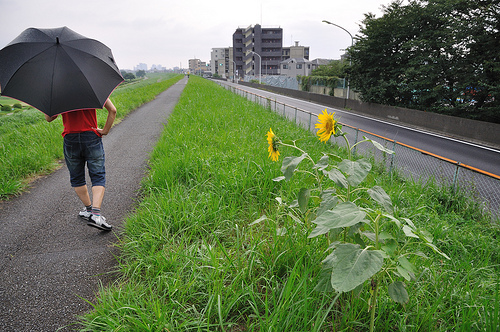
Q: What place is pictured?
A: It is a path.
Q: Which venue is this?
A: This is a path.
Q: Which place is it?
A: It is a path.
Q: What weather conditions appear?
A: It is overcast.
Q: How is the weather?
A: It is overcast.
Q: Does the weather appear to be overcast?
A: Yes, it is overcast.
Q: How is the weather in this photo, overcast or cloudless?
A: It is overcast.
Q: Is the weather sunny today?
A: No, it is overcast.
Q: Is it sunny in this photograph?
A: No, it is overcast.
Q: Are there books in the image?
A: No, there are no books.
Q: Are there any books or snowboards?
A: No, there are no books or snowboards.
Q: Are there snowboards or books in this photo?
A: No, there are no books or snowboards.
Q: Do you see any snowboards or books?
A: No, there are no books or snowboards.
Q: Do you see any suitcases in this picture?
A: No, there are no suitcases.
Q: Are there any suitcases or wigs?
A: No, there are no suitcases or wigs.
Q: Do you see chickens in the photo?
A: No, there are no chickens.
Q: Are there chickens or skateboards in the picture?
A: No, there are no chickens or skateboards.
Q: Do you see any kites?
A: No, there are no kites.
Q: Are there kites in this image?
A: No, there are no kites.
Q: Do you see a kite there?
A: No, there are no kites.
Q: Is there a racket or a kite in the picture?
A: No, there are no kites or rackets.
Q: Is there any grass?
A: Yes, there is grass.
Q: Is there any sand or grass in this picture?
A: Yes, there is grass.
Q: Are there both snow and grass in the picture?
A: No, there is grass but no snow.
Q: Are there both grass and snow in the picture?
A: No, there is grass but no snow.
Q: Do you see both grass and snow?
A: No, there is grass but no snow.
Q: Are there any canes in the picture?
A: No, there are no canes.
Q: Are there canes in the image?
A: No, there are no canes.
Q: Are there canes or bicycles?
A: No, there are no canes or bicycles.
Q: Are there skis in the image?
A: No, there are no skis.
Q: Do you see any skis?
A: No, there are no skis.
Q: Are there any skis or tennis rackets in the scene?
A: No, there are no skis or tennis rackets.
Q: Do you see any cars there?
A: No, there are no cars.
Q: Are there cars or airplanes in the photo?
A: No, there are no cars or airplanes.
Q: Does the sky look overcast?
A: Yes, the sky is overcast.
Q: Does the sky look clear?
A: No, the sky is overcast.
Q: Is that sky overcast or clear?
A: The sky is overcast.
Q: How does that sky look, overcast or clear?
A: The sky is overcast.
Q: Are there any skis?
A: No, there are no skis.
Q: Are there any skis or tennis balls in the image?
A: No, there are no skis or tennis balls.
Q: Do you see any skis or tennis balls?
A: No, there are no skis or tennis balls.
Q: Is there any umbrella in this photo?
A: Yes, there is an umbrella.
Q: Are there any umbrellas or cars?
A: Yes, there is an umbrella.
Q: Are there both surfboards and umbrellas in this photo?
A: No, there is an umbrella but no surfboards.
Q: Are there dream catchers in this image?
A: No, there are no dream catchers.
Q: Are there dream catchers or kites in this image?
A: No, there are no dream catchers or kites.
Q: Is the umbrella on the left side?
A: Yes, the umbrella is on the left of the image.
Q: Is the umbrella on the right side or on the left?
A: The umbrella is on the left of the image.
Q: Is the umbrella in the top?
A: Yes, the umbrella is in the top of the image.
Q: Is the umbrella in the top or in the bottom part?
A: The umbrella is in the top of the image.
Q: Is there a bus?
A: No, there are no buses.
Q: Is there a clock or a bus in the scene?
A: No, there are no buses or clocks.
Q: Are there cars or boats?
A: No, there are no cars or boats.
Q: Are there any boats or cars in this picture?
A: No, there are no cars or boats.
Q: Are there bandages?
A: No, there are no bandages.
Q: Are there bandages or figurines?
A: No, there are no bandages or figurines.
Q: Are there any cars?
A: No, there are no cars.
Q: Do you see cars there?
A: No, there are no cars.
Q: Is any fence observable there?
A: Yes, there is a fence.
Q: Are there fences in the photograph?
A: Yes, there is a fence.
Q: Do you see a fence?
A: Yes, there is a fence.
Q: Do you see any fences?
A: Yes, there is a fence.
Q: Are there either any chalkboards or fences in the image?
A: Yes, there is a fence.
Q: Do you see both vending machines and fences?
A: No, there is a fence but no vending machines.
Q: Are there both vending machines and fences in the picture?
A: No, there is a fence but no vending machines.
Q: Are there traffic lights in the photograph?
A: No, there are no traffic lights.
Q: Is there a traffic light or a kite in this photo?
A: No, there are no traffic lights or kites.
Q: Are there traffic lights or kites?
A: No, there are no traffic lights or kites.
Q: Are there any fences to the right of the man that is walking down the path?
A: Yes, there is a fence to the right of the man.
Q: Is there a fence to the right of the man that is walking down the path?
A: Yes, there is a fence to the right of the man.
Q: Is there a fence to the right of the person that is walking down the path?
A: Yes, there is a fence to the right of the man.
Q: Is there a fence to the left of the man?
A: No, the fence is to the right of the man.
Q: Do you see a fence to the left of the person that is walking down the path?
A: No, the fence is to the right of the man.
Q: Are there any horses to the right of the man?
A: No, there is a fence to the right of the man.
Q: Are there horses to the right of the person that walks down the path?
A: No, there is a fence to the right of the man.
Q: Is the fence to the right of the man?
A: Yes, the fence is to the right of the man.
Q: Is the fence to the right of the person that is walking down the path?
A: Yes, the fence is to the right of the man.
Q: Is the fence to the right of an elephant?
A: No, the fence is to the right of the man.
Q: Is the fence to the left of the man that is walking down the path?
A: No, the fence is to the right of the man.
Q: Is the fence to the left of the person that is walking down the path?
A: No, the fence is to the right of the man.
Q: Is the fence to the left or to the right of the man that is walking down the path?
A: The fence is to the right of the man.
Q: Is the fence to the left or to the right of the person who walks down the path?
A: The fence is to the right of the man.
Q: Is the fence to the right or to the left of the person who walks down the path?
A: The fence is to the right of the man.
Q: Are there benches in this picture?
A: No, there are no benches.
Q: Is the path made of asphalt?
A: Yes, the path is made of asphalt.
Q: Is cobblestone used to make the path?
A: No, the path is made of asphalt.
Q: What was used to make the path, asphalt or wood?
A: The path is made of asphalt.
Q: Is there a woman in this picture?
A: No, there are no women.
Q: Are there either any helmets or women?
A: No, there are no women or helmets.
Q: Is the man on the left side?
A: Yes, the man is on the left of the image.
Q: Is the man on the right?
A: No, the man is on the left of the image.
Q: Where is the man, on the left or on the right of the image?
A: The man is on the left of the image.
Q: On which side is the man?
A: The man is on the left of the image.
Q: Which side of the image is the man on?
A: The man is on the left of the image.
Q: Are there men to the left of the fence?
A: Yes, there is a man to the left of the fence.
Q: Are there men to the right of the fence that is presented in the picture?
A: No, the man is to the left of the fence.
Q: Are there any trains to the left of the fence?
A: No, there is a man to the left of the fence.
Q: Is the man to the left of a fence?
A: Yes, the man is to the left of a fence.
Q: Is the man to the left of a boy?
A: No, the man is to the left of a fence.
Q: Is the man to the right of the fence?
A: No, the man is to the left of the fence.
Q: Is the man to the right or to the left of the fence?
A: The man is to the left of the fence.